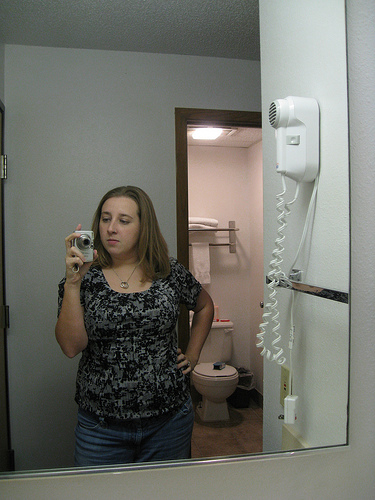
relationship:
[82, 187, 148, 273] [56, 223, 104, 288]
woman holding camera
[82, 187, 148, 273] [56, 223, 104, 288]
woman with camera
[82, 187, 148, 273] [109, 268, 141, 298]
woman wearing a necklace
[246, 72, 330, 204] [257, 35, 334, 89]
hair dryer on wall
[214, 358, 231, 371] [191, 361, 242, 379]
box on toilet cover